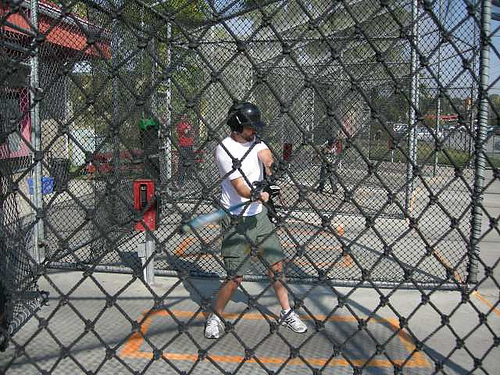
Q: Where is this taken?
A: Batting cages.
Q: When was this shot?
A: Daytime.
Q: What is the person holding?
A: Baseball bat.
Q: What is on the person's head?
A: Helmet.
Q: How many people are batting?
A: 2.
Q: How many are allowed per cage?
A: 1.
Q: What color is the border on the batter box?
A: Yellow.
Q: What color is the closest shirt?
A: White.